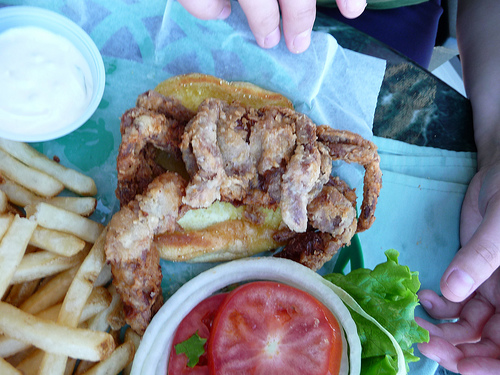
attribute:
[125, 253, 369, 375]
onion — sliced,   three , white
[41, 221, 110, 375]
french fry — fried, piled, portioned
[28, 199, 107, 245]
french fry — fried, piled, portioned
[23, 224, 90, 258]
french fry — fried, piled, portioned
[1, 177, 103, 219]
french fry — fried, piled, One , portioned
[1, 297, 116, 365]
french fry — fried, piled, portioned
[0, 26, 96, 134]
condiment — white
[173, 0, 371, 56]
hand — person's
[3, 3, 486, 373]
table — marble, green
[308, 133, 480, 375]
napkin — white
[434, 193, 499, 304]
thumb — part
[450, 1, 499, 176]
arm — person's, part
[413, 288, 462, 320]
finger — person's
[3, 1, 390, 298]
wrapper — blue, light sky blue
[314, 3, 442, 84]
pants — blue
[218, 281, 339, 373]
tomato — sliced, part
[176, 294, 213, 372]
tomato — sliced, part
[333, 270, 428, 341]
lettuce — green, leafed, part  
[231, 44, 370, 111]
cloth — part 